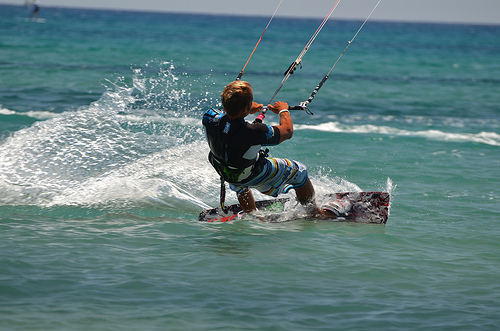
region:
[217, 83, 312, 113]
bar wakeboarder is holding onto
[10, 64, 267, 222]
spray kicked up by wakeboarder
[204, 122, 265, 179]
black life vest of wakeboarder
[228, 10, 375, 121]
bar and rope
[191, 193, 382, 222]
black board wakeboarder is riding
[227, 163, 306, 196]
striped board shorts of wakeboarder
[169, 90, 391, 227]
wakeboarder leaning back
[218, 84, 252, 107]
wet blonde hair of wakeboarder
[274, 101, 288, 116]
wristband wakeboarder is wearing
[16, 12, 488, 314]
ocean wakeboarder is in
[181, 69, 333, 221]
man para surfing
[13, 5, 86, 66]
white clouds in blue sky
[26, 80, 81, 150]
white and green ocean waves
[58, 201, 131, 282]
white and green ocean waves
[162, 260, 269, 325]
white and green ocean waves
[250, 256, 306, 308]
white and green ocean waves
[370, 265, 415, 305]
white and green ocean waves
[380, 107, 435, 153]
white and green ocean waves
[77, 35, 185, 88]
white and green ocean waves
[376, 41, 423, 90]
white and green ocean waves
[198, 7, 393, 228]
surfer hanging onto horizontal rod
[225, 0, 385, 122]
connector and cords attached to rods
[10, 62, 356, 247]
water splashing on one side of board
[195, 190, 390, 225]
edge of dark board on water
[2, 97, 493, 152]
line of white water across surfer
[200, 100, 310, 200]
blue and orange stripes on outfit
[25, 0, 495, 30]
gray sky over horizon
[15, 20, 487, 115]
dark lines across ocean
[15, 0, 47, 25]
surfer in distance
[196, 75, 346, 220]
surfer leaning backwards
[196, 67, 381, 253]
para surfer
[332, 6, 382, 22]
white clouds in blue sky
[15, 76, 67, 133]
green and white waves in coean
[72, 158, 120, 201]
green and white waves in coean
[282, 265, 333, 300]
green and white waves in coean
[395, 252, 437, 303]
green and white waves in coean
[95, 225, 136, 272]
green and white waves in coean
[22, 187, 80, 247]
green and white waves in coean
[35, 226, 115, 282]
green and white waves in coean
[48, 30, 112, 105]
green and white waves in coean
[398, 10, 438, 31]
white clouds in blue sky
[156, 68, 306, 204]
man wearing wet suit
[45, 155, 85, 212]
white and green ocean waves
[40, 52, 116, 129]
white and green ocean waves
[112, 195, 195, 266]
white and green ocean waves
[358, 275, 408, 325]
white and green ocean waves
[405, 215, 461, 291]
white and green ocean waves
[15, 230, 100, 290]
white and green ocean waves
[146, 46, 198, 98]
white and green ocean waves